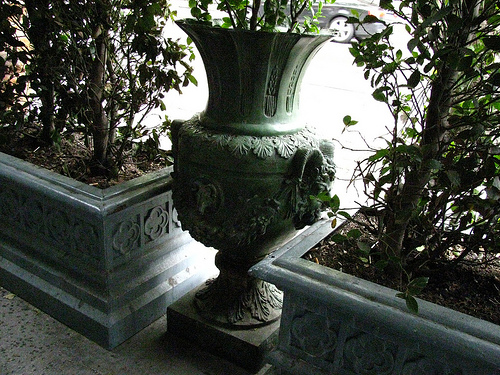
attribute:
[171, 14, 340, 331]
vase — green, stone, concrette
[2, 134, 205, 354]
planter — stone, sunny, patterned, rectangular, carved, concrete, grey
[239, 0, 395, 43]
car — black, parked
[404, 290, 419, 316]
leaf — small, green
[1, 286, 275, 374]
floor — gray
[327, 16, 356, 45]
wheel — white, chrome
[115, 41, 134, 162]
branch — brown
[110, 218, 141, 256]
symbol — clover